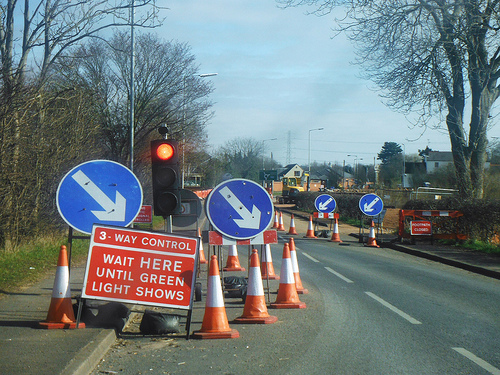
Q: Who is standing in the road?
A: No one.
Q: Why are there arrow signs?
A: To redirect traffic.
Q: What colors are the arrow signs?
A: Blue, White.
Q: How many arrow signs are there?
A: Four.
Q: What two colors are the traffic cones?
A: Orange, White.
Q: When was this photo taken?
A: Daytime.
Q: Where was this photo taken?
A: Near road construction.